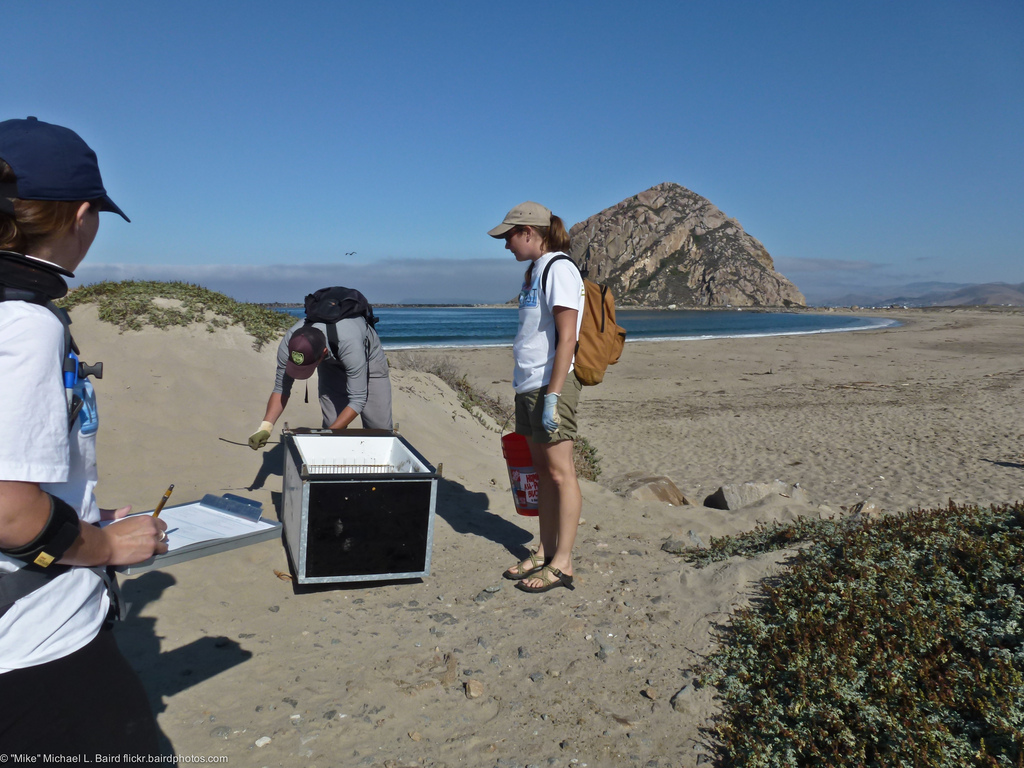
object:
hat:
[0, 113, 145, 230]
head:
[2, 111, 115, 269]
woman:
[3, 111, 175, 757]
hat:
[266, 315, 346, 397]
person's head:
[269, 321, 378, 447]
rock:
[539, 162, 794, 323]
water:
[559, 284, 861, 351]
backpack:
[287, 271, 386, 332]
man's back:
[269, 279, 397, 362]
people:
[0, 78, 655, 554]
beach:
[8, 63, 1018, 736]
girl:
[471, 184, 610, 403]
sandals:
[495, 536, 590, 608]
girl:
[454, 169, 645, 342]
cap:
[488, 190, 587, 285]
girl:
[469, 195, 604, 419]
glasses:
[496, 214, 529, 247]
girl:
[466, 169, 631, 347]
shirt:
[506, 247, 586, 390]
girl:
[480, 180, 576, 289]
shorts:
[503, 357, 583, 452]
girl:
[480, 175, 600, 336]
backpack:
[570, 258, 638, 403]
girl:
[469, 184, 638, 418]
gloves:
[525, 367, 564, 445]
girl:
[454, 191, 605, 362]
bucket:
[496, 409, 570, 526]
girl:
[466, 167, 638, 317]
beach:
[153, 341, 961, 763]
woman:
[460, 173, 603, 325]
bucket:
[577, 262, 629, 390]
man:
[250, 273, 374, 401]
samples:
[214, 406, 286, 458]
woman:
[471, 180, 592, 334]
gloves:
[536, 392, 575, 435]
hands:
[514, 367, 599, 463]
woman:
[455, 167, 622, 330]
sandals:
[506, 531, 589, 594]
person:
[2, 102, 164, 347]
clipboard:
[104, 458, 317, 625]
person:
[2, 106, 160, 424]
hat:
[5, 108, 207, 319]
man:
[244, 284, 391, 408]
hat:
[277, 312, 324, 390]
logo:
[280, 341, 304, 368]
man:
[255, 312, 381, 429]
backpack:
[298, 275, 393, 345]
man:
[250, 289, 401, 413]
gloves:
[239, 419, 275, 462]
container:
[277, 406, 442, 597]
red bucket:
[503, 422, 547, 518]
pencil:
[148, 479, 184, 522]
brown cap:
[487, 206, 561, 241]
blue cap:
[0, 119, 134, 232]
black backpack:
[304, 279, 384, 366]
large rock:
[569, 182, 812, 317]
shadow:
[425, 454, 535, 552]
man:
[250, 281, 406, 448]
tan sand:
[128, 340, 252, 446]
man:
[2, 109, 185, 758]